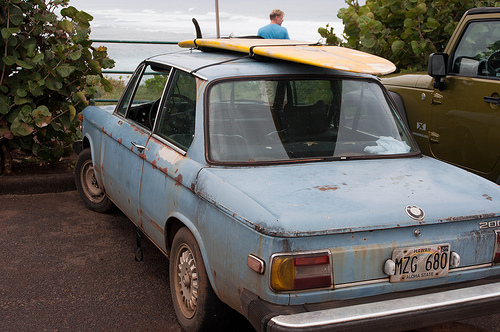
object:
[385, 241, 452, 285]
license plate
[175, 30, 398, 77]
surfboard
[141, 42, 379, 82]
roof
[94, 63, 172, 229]
door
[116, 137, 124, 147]
rust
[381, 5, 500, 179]
jeep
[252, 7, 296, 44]
man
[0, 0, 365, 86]
ocean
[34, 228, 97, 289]
parking lot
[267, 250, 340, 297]
backlights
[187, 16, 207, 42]
surf fin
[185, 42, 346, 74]
straps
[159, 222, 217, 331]
back tire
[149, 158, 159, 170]
spots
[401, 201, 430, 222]
logo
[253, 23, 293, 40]
shirt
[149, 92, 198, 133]
wheel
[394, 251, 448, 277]
plate number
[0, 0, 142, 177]
plant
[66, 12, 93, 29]
leaves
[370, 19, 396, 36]
tree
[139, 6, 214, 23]
sky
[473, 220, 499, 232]
number plates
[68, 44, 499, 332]
bmw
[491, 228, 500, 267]
tail light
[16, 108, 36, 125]
foliage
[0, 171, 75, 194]
curb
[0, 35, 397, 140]
fence